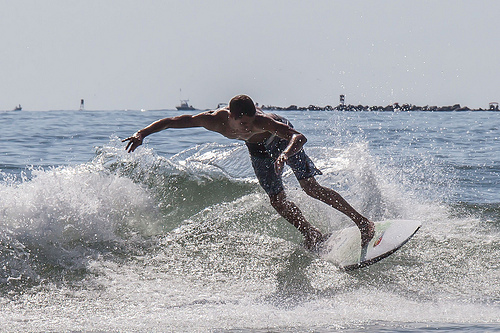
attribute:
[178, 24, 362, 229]
surfer — riding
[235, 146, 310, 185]
shorts — blue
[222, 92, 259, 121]
hair — short, dark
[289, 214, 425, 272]
surfboard — white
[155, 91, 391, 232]
man — riding, shirtless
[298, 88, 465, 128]
land — distant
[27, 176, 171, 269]
wave — foamy, covered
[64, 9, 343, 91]
sky — hazy, open, above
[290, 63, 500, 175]
water — still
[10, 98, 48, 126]
boat — distant, sailing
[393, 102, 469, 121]
rocks — large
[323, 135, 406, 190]
foam — splashing